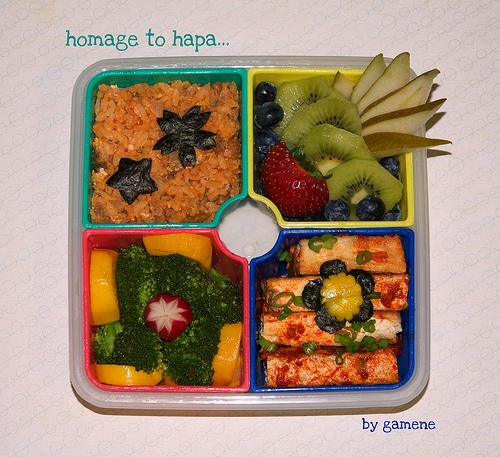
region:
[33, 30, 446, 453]
Square container full of food.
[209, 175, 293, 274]
Dipping sauce in the middle.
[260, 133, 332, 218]
Strawberry in the container.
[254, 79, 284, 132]
Two blueberries in the container.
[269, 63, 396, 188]
Kiwi in the container.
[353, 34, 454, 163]
Pears in the container.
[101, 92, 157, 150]
Rice in the container.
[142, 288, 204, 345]
Red radish in the container.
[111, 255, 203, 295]
Broccoli in the container.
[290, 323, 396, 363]
Green onions sprinkled on top.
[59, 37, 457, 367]
a container with sections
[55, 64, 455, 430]
a contaner with foods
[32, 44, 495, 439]
rice in a container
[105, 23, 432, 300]
fruit in a container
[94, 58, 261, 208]
fruit in teal container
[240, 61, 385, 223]
fruit in yellow container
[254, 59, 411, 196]
a container with kiwi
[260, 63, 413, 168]
a container with blueberries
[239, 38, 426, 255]
a container with yellow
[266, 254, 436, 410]
a container with burritos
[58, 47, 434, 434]
square trey of food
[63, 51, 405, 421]
four compartment trey of food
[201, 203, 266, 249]
hollow center of trey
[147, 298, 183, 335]
red vegetable in center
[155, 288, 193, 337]
radish in middle of trey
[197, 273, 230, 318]
broccoli in the trey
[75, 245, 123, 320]
orange piece of food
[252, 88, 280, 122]
blue berries in trey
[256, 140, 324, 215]
part of a strawberry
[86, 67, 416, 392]
Individual sections in the tray.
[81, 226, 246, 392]
Red square shaped dish in the tray.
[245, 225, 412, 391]
Blue square shaped dish in the tray.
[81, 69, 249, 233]
A green square shaped dish in the tray.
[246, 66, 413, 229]
A yellow square shaped dish in the tray.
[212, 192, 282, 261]
Round sauce container in the middle of the tray.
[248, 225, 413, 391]
Enchiladas with red sauce in a blue dish.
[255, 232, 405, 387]
Sliced jalapenos on top of enchiladas.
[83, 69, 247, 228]
Spanish rice in the green dish.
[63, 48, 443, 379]
a tray of difrent foods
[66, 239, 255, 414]
trayiis redin color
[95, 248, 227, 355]
vegetables are green in color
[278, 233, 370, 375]
fruits are brown incolor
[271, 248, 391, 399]
tray is blue in color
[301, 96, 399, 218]
fruits are black in ccolor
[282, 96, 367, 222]
tray has fruitd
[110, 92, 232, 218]
tray has carbohydrates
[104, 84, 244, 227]
tray is green in color